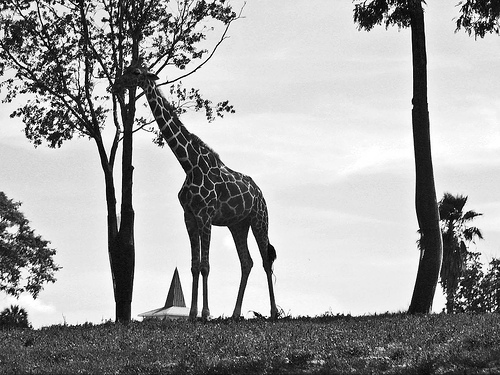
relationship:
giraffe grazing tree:
[110, 49, 281, 324] [4, 2, 237, 315]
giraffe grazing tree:
[116, 54, 279, 322] [4, 2, 237, 315]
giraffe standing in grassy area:
[110, 49, 281, 324] [0, 309, 498, 373]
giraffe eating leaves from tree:
[95, 37, 302, 322] [4, 2, 237, 315]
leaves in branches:
[0, 0, 245, 152] [2, 0, 245, 148]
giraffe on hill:
[110, 49, 281, 324] [0, 309, 500, 374]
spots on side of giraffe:
[224, 181, 239, 197] [110, 49, 281, 324]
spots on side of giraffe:
[237, 188, 254, 203] [110, 49, 281, 324]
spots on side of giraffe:
[173, 129, 185, 142] [110, 49, 281, 324]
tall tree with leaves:
[0, 0, 244, 309] [0, 0, 245, 152]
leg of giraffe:
[253, 230, 287, 317] [122, 60, 287, 334]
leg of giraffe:
[226, 225, 253, 322] [122, 60, 287, 334]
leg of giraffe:
[179, 222, 200, 323] [122, 60, 287, 334]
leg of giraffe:
[197, 219, 212, 320] [122, 60, 287, 334]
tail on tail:
[264, 242, 276, 289] [262, 235, 280, 290]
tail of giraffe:
[262, 235, 280, 290] [110, 49, 281, 324]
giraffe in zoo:
[110, 49, 281, 324] [6, 1, 498, 365]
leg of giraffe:
[226, 220, 253, 322] [110, 49, 281, 324]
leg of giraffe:
[197, 219, 212, 320] [110, 49, 281, 324]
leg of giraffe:
[184, 217, 200, 321] [74, 57, 356, 340]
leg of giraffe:
[199, 219, 212, 320] [74, 57, 356, 340]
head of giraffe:
[108, 52, 158, 102] [111, 67, 286, 322]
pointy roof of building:
[164, 266, 186, 306] [132, 262, 197, 320]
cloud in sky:
[230, 52, 403, 92] [242, 40, 397, 165]